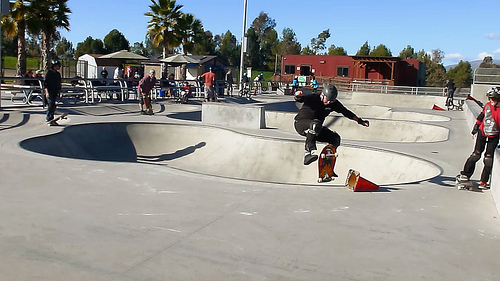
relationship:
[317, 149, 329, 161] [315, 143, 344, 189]
wheel of skateboard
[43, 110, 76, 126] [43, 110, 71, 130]
edge of skateboard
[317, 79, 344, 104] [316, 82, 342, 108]
helmet on head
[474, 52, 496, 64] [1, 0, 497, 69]
cloud in sky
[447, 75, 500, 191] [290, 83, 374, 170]
skater watching skater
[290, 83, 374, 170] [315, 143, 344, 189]
skater using skateboard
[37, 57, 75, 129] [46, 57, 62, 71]
skater wearing helmet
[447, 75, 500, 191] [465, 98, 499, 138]
man in shirt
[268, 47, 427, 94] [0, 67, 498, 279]
building near park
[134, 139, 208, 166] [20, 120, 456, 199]
shadow in pool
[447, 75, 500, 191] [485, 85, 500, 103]
skater wearing helmet